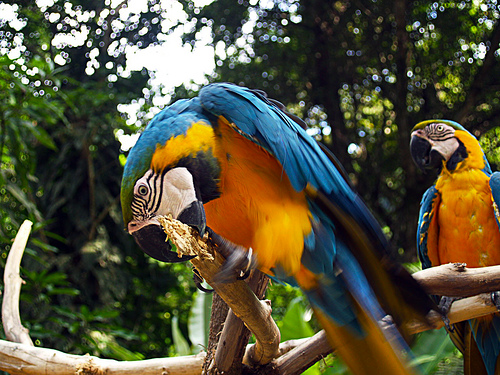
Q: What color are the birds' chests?
A: Orange.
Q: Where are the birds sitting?
A: On tree limbs.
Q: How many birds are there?
A: 2.